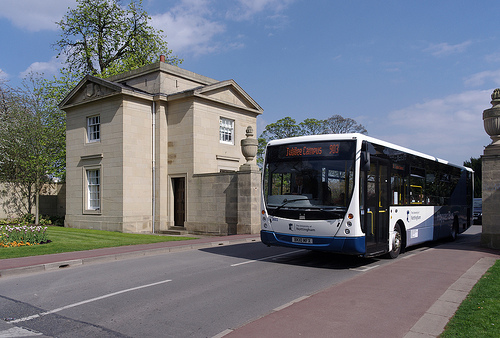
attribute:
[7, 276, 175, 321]
line — white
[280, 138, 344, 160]
letters — red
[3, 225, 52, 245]
flowers — long, stemmed, purple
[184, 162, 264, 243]
wall — brick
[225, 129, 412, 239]
bus — blue, white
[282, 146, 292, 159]
letter — red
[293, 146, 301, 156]
letter — red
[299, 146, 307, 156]
letter — red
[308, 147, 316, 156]
letter — red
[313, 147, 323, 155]
letter — red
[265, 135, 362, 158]
sign — electronic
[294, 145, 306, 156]
letter — red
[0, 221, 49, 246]
flower bed — maintained